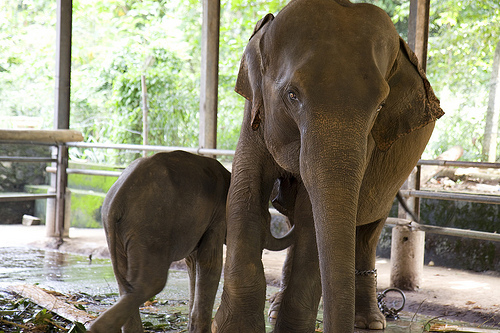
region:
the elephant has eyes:
[216, 25, 412, 202]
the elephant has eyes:
[256, 33, 489, 234]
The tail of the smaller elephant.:
[97, 195, 138, 298]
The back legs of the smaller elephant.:
[101, 256, 167, 331]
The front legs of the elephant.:
[182, 233, 224, 329]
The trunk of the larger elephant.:
[300, 125, 364, 329]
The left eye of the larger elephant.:
[282, 82, 302, 107]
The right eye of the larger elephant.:
[375, 95, 388, 111]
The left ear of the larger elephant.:
[234, 14, 277, 126]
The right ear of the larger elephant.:
[389, 34, 442, 152]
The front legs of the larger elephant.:
[234, 155, 329, 331]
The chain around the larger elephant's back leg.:
[343, 250, 414, 329]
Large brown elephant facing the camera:
[217, 6, 454, 331]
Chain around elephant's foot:
[355, 263, 417, 323]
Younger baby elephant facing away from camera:
[85, 125, 277, 331]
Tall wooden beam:
[55, 3, 79, 240]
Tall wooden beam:
[192, 5, 234, 173]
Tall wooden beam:
[400, 6, 433, 236]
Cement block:
[392, 225, 424, 295]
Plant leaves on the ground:
[5, 285, 173, 331]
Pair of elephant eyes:
[282, 69, 399, 129]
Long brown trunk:
[291, 139, 374, 331]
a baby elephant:
[86, 144, 219, 328]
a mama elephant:
[220, 3, 417, 328]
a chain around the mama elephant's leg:
[347, 267, 413, 317]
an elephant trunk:
[283, 76, 385, 331]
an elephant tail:
[97, 190, 137, 307]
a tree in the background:
[71, 3, 203, 150]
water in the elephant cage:
[2, 241, 114, 314]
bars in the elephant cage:
[391, 150, 498, 313]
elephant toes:
[352, 311, 387, 331]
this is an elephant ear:
[381, 25, 443, 145]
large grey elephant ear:
[368, 35, 445, 152]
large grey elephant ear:
[230, 8, 274, 134]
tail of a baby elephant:
[105, 207, 135, 297]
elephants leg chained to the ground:
[350, 221, 413, 332]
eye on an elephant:
[281, 83, 304, 110]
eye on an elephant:
[374, 96, 389, 118]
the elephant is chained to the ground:
[204, 2, 476, 332]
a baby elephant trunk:
[262, 211, 297, 253]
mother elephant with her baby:
[76, 0, 455, 332]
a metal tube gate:
[57, 128, 498, 276]